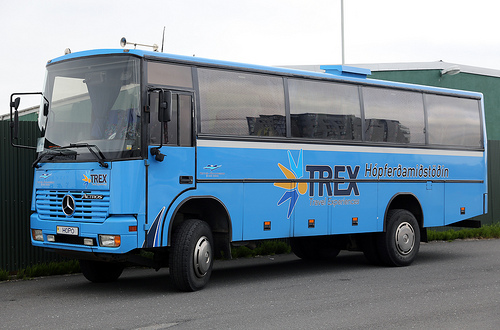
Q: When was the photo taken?
A: During the day.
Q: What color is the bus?
A: Blue.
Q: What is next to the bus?
A: A fence.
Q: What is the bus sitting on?
A: The street.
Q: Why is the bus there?
A: To give people a ride.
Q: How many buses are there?
A: One.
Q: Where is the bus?
A: Next to a building.